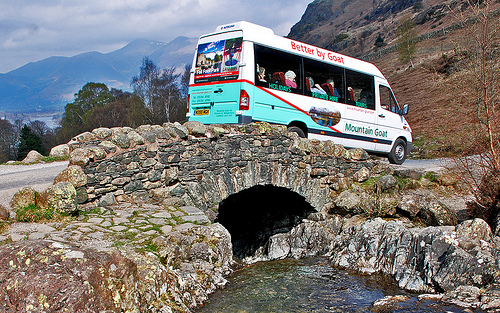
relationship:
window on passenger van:
[343, 65, 376, 112] [183, 20, 414, 164]